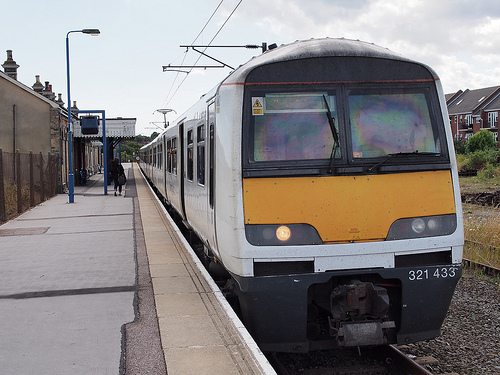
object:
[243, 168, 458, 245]
panel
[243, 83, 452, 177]
windshield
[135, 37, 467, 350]
train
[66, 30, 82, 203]
pole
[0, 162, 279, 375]
floor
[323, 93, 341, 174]
wiper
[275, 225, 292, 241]
light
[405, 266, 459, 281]
number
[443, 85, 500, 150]
house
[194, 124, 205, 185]
window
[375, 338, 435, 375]
rail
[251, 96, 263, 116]
sticker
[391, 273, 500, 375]
gravel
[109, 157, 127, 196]
woman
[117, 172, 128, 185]
bag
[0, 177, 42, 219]
mural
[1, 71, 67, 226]
wall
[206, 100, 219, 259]
door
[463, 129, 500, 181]
tree